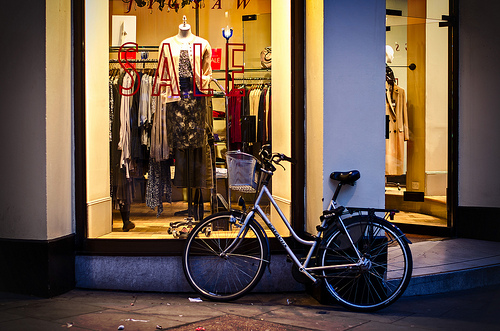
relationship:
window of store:
[112, 1, 283, 234] [2, 2, 494, 238]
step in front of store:
[413, 245, 500, 292] [2, 2, 494, 238]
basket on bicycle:
[219, 150, 262, 188] [182, 145, 418, 313]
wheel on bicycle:
[179, 210, 270, 305] [182, 145, 418, 313]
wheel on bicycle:
[321, 214, 422, 320] [182, 145, 418, 313]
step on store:
[413, 245, 500, 292] [2, 2, 494, 238]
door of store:
[386, 17, 448, 229] [2, 2, 494, 238]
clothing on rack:
[231, 87, 273, 150] [222, 70, 270, 85]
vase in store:
[112, 20, 141, 45] [2, 2, 494, 238]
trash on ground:
[177, 291, 204, 315] [119, 301, 184, 331]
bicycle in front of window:
[182, 145, 418, 313] [112, 1, 283, 234]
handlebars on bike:
[253, 143, 295, 169] [182, 145, 418, 313]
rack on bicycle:
[321, 200, 348, 222] [182, 145, 418, 313]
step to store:
[413, 245, 500, 292] [2, 2, 494, 238]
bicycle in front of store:
[182, 145, 418, 313] [2, 2, 494, 238]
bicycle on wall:
[182, 145, 418, 313] [323, 1, 387, 184]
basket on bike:
[219, 150, 262, 188] [182, 145, 418, 313]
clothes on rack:
[231, 87, 273, 150] [222, 70, 270, 85]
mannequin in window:
[159, 16, 216, 225] [112, 1, 283, 234]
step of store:
[413, 245, 500, 292] [2, 2, 494, 238]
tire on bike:
[179, 210, 270, 305] [182, 145, 418, 313]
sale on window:
[121, 37, 249, 104] [112, 1, 283, 234]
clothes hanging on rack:
[231, 87, 273, 150] [222, 70, 270, 85]